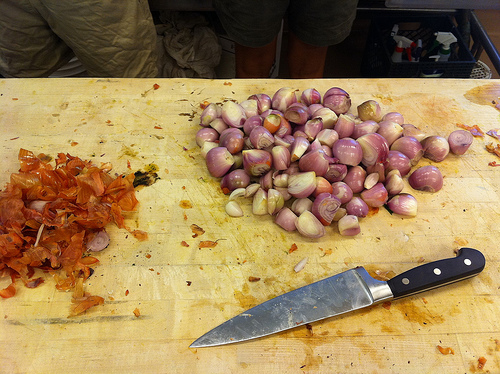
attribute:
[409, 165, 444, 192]
shallot — cut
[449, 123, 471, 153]
shallot — cut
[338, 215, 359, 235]
shallot — cut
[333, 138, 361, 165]
shallot — cut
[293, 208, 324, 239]
shallot — cut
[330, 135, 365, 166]
onion — chopped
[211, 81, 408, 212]
onions — red, purple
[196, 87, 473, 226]
onions — purple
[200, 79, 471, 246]
onions — laying, small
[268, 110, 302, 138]
shallot — cut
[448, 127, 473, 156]
shallot — cut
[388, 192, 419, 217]
shallot — cut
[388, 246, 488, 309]
handle — part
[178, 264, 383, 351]
blade — sharp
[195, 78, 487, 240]
onions — stemless, skinless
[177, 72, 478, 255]
onion — part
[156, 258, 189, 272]
line — part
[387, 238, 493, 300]
handle — black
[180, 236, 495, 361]
knife — chopping, large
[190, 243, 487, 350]
knife — metal, part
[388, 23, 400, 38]
products — cleaning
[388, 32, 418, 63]
products — cleaning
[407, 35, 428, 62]
products — cleaning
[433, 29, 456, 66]
products — cleaning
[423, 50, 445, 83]
products — cleaning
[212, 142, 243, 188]
piece — small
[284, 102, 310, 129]
piece — small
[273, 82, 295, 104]
shallot — cut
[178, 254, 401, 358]
area — metallic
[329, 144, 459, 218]
onion — chopped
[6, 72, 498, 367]
board — cutting